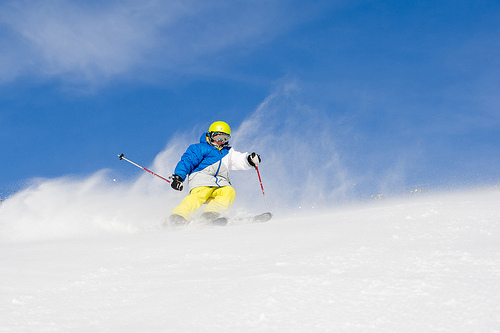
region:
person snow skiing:
[116, 119, 276, 229]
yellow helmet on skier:
[209, 116, 234, 136]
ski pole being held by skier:
[114, 147, 182, 192]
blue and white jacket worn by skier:
[177, 132, 256, 189]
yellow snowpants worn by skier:
[171, 185, 233, 221]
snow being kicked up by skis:
[2, 175, 149, 239]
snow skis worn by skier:
[157, 213, 272, 226]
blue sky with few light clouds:
[3, 2, 498, 169]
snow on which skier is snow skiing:
[4, 215, 499, 330]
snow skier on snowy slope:
[116, 121, 283, 228]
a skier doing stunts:
[112, 116, 277, 238]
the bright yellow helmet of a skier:
[200, 116, 231, 146]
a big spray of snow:
[1, 71, 380, 268]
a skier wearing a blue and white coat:
[162, 111, 269, 228]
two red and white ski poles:
[106, 151, 284, 233]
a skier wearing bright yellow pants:
[170, 118, 266, 228]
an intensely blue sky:
[0, 4, 496, 220]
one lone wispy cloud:
[0, 0, 201, 106]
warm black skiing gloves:
[166, 149, 270, 196]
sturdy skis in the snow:
[141, 203, 280, 235]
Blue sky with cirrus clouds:
[23, 19, 183, 106]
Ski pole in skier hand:
[112, 146, 184, 199]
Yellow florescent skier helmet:
[198, 113, 236, 150]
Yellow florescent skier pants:
[168, 185, 246, 239]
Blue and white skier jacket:
[181, 141, 255, 195]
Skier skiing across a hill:
[123, 121, 289, 236]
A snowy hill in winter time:
[270, 188, 437, 293]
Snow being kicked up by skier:
[9, 182, 196, 274]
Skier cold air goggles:
[208, 129, 230, 143]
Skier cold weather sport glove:
[162, 173, 188, 193]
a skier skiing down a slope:
[130, 105, 335, 256]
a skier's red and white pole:
[115, 141, 195, 196]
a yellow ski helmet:
[200, 112, 240, 134]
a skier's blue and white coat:
[180, 135, 245, 185]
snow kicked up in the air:
[37, 136, 348, 216]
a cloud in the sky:
[15, 0, 245, 95]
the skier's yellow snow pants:
[165, 185, 240, 220]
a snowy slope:
[26, 223, 471, 324]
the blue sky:
[306, 5, 497, 57]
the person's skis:
[132, 212, 277, 236]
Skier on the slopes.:
[81, 78, 290, 325]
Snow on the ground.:
[307, 212, 409, 299]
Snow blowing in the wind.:
[11, 133, 323, 298]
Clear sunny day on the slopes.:
[111, 26, 366, 313]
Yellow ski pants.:
[128, 120, 290, 249]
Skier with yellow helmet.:
[101, 62, 359, 294]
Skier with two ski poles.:
[111, 90, 341, 244]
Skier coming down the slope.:
[78, 71, 253, 243]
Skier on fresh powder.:
[84, 101, 254, 247]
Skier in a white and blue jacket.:
[86, 58, 351, 325]